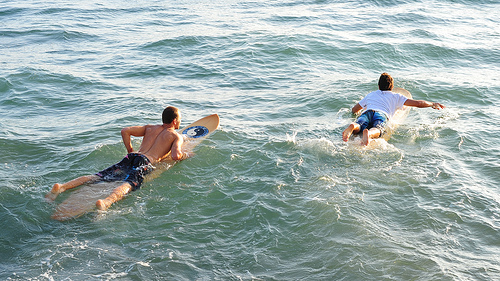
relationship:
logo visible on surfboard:
[185, 107, 210, 143] [49, 112, 221, 222]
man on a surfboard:
[354, 69, 405, 143] [394, 81, 412, 128]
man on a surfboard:
[41, 97, 193, 233] [151, 108, 218, 180]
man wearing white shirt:
[354, 69, 405, 143] [359, 90, 406, 116]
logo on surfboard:
[183, 122, 207, 137] [65, 114, 225, 224]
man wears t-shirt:
[354, 69, 405, 143] [357, 89, 406, 118]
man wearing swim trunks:
[41, 97, 193, 233] [97, 151, 157, 191]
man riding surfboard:
[354, 69, 405, 143] [377, 87, 418, 158]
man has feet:
[41, 97, 193, 233] [48, 180, 106, 218]